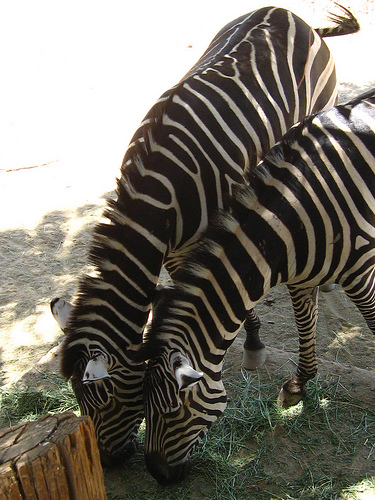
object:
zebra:
[51, 3, 375, 469]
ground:
[1, 164, 370, 499]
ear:
[82, 355, 111, 385]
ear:
[49, 295, 76, 332]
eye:
[165, 408, 182, 418]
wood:
[2, 410, 105, 498]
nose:
[146, 449, 169, 482]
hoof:
[240, 348, 269, 371]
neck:
[74, 182, 170, 344]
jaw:
[197, 377, 228, 433]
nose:
[99, 445, 115, 470]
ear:
[175, 365, 206, 389]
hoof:
[277, 376, 304, 408]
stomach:
[287, 261, 353, 292]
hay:
[292, 441, 362, 491]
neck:
[154, 263, 269, 365]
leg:
[276, 283, 321, 411]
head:
[48, 296, 146, 468]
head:
[145, 333, 228, 484]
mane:
[65, 178, 125, 375]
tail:
[311, 0, 363, 38]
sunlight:
[1, 307, 60, 393]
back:
[142, 6, 294, 151]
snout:
[146, 443, 193, 486]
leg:
[339, 274, 374, 332]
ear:
[123, 340, 167, 365]